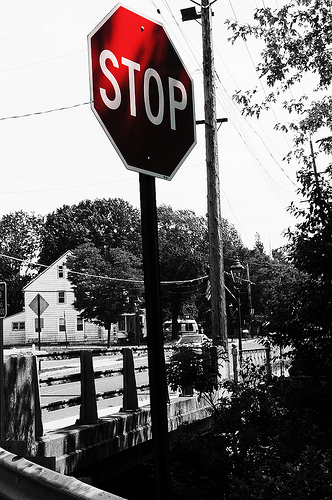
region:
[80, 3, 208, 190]
stop sign on pole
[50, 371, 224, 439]
bridge for vehicle traffic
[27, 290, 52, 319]
back of traffic sign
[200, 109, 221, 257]
telephone pole on side of road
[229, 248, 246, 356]
street light on sidewalk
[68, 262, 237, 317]
wires in the air above sidewalk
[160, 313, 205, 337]
van parked in driveway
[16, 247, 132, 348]
three story house on street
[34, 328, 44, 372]
pole for traffic signs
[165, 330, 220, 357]
car driving toward bridge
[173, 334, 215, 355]
a car traveling on a street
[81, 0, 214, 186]
a red stop sign has eight sides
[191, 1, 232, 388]
a large utility pole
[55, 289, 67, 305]
an open window to a house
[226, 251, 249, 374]
an old fashioned street light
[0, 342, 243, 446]
the railings of a bridge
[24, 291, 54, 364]
a street sign turned away from view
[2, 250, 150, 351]
a very large white house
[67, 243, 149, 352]
a large tree in the yard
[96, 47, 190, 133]
the word stop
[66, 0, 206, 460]
red and white traffic sign on pole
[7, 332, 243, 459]
short bridge with side barrier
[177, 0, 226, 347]
tall and rough utility pole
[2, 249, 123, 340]
white clapboard house by road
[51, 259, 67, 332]
three stories of windows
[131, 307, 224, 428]
car on top of bridge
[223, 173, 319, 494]
large tree growing near overpass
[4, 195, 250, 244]
scalloped edge of tree tops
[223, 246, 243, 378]
post with lantern on top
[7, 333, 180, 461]
light and shadow on overpass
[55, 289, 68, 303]
a window in a house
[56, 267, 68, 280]
a window in a house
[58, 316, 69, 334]
a window in a house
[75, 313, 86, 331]
a window in a house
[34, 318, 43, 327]
a window in a house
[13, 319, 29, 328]
a window in a house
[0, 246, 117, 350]
a nice house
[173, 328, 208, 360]
a parked vehicle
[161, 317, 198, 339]
a parked vehicle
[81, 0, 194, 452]
a stop sign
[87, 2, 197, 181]
a red stop sign mounted a pole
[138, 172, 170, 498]
a pole in which a stop sign is mounted on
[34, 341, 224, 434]
a fence on the overpass road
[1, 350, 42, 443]
a concrete column support for the fence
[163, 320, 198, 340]
a camper van parked at a house across the street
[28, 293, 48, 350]
a yield warning sign facing the oncoming traffic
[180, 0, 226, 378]
a telephone pole on the sidewalk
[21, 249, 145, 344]
a white wooden house across the street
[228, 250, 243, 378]
a street lamp and pole along the sidewalk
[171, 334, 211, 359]
a white car driving along the overpass